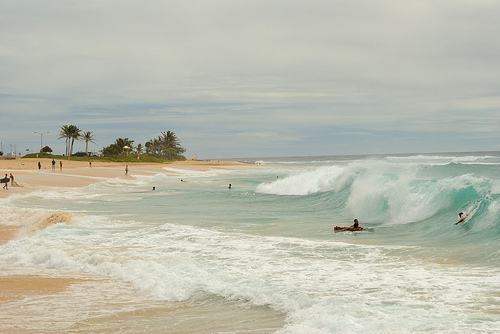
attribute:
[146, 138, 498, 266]
water — turbulent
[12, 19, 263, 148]
sky — dull blue, cloud-filled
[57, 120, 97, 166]
palmtrees — palm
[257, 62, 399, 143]
sky — blue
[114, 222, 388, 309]
tide — strong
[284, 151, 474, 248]
water — white-capped, blue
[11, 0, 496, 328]
scene — summer-type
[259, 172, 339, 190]
surf — white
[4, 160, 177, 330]
sand — buff-colored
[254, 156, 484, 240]
wave — big